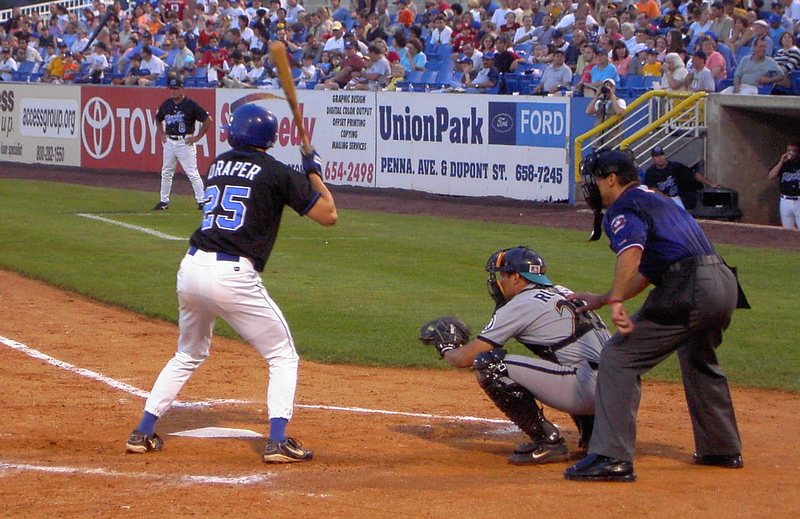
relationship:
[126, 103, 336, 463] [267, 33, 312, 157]
body about to bat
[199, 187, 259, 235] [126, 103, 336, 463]
number on body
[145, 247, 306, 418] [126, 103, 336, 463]
pants on body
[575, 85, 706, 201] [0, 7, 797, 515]
stairs onto field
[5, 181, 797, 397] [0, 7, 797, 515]
grass at field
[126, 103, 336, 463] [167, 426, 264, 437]
body at diamond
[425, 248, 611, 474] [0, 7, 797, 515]
catcher on field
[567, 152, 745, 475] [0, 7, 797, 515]
umpire on field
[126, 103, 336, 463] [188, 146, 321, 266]
body on shirt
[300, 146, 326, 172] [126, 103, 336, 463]
glove of body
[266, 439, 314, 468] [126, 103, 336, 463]
shoe of body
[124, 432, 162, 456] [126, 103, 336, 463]
shoe of body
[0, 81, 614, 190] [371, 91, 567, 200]
wall of bleacher